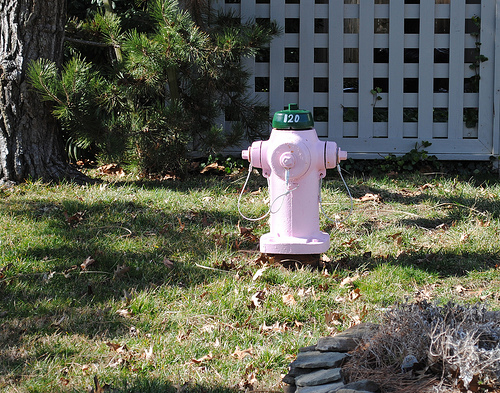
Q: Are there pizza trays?
A: No, there are no pizza trays.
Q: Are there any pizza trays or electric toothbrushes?
A: No, there are no pizza trays or electric toothbrushes.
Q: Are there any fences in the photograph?
A: Yes, there is a fence.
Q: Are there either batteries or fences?
A: Yes, there is a fence.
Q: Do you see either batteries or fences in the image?
A: Yes, there is a fence.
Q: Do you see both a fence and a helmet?
A: No, there is a fence but no helmets.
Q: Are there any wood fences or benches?
A: Yes, there is a wood fence.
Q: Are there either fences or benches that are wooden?
A: Yes, the fence is wooden.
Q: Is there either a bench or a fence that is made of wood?
A: Yes, the fence is made of wood.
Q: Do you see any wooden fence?
A: Yes, there is a wood fence.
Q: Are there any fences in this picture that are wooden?
A: Yes, there is a fence that is wooden.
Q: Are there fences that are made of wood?
A: Yes, there is a fence that is made of wood.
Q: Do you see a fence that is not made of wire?
A: Yes, there is a fence that is made of wood.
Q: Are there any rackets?
A: No, there are no rackets.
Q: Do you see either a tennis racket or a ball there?
A: No, there are no rackets or balls.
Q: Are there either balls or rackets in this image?
A: No, there are no rackets or balls.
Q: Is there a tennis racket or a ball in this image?
A: No, there are no rackets or balls.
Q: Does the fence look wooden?
A: Yes, the fence is wooden.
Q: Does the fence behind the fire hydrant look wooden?
A: Yes, the fence is wooden.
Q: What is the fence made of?
A: The fence is made of wood.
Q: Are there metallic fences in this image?
A: No, there is a fence but it is wooden.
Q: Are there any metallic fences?
A: No, there is a fence but it is wooden.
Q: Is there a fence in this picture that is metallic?
A: No, there is a fence but it is wooden.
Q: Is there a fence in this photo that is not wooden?
A: No, there is a fence but it is wooden.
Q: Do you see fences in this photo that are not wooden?
A: No, there is a fence but it is wooden.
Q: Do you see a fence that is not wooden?
A: No, there is a fence but it is wooden.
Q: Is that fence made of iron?
A: No, the fence is made of wood.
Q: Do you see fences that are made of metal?
A: No, there is a fence but it is made of wood.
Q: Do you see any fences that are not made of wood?
A: No, there is a fence but it is made of wood.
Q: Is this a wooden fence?
A: Yes, this is a wooden fence.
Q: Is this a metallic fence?
A: No, this is a wooden fence.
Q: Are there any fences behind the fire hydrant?
A: Yes, there is a fence behind the fire hydrant.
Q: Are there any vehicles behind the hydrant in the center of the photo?
A: No, there is a fence behind the hydrant.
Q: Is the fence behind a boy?
A: No, the fence is behind the hydrant.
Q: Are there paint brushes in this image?
A: No, there are no paint brushes.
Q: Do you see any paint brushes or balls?
A: No, there are no paint brushes or balls.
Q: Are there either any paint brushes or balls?
A: No, there are no paint brushes or balls.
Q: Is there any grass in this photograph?
A: Yes, there is grass.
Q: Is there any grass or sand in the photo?
A: Yes, there is grass.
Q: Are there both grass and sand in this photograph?
A: No, there is grass but no sand.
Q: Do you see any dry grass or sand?
A: Yes, there is dry grass.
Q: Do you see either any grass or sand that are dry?
A: Yes, the grass is dry.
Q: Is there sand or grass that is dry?
A: Yes, the grass is dry.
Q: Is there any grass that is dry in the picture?
A: Yes, there is dry grass.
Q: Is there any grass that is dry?
A: Yes, there is grass that is dry.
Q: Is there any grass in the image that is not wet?
A: Yes, there is dry grass.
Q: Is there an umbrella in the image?
A: No, there are no umbrellas.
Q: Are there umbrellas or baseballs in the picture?
A: No, there are no umbrellas or baseballs.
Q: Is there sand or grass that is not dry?
A: No, there is grass but it is dry.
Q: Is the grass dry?
A: Yes, the grass is dry.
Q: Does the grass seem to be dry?
A: Yes, the grass is dry.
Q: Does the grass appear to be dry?
A: Yes, the grass is dry.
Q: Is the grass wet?
A: No, the grass is dry.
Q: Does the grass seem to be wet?
A: No, the grass is dry.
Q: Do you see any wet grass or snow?
A: No, there is grass but it is dry.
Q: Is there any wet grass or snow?
A: No, there is grass but it is dry.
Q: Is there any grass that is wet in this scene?
A: No, there is grass but it is dry.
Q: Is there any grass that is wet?
A: No, there is grass but it is dry.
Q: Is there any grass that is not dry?
A: No, there is grass but it is dry.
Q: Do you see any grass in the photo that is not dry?
A: No, there is grass but it is dry.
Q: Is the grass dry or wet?
A: The grass is dry.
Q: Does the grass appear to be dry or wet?
A: The grass is dry.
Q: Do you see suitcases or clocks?
A: No, there are no clocks or suitcases.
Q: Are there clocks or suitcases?
A: No, there are no clocks or suitcases.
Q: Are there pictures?
A: No, there are no pictures.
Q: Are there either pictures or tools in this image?
A: No, there are no pictures or tools.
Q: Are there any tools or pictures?
A: No, there are no pictures or tools.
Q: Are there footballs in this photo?
A: No, there are no footballs.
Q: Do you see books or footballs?
A: No, there are no footballs or books.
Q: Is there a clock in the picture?
A: No, there are no clocks.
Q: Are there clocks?
A: No, there are no clocks.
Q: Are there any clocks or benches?
A: No, there are no clocks or benches.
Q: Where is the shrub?
A: The shrub is at the trunk.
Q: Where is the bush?
A: The shrub is at the trunk.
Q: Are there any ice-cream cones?
A: No, there are no ice-cream cones.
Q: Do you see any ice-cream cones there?
A: No, there are no ice-cream cones.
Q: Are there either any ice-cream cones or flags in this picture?
A: No, there are no ice-cream cones or flags.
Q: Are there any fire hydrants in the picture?
A: Yes, there is a fire hydrant.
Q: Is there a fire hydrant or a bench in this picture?
A: Yes, there is a fire hydrant.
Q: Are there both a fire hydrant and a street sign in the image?
A: No, there is a fire hydrant but no street signs.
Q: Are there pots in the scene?
A: No, there are no pots.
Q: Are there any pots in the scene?
A: No, there are no pots.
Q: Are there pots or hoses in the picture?
A: No, there are no pots or hoses.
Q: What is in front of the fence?
A: The hydrant is in front of the fence.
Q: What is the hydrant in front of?
A: The hydrant is in front of the fence.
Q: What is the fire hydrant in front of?
A: The hydrant is in front of the fence.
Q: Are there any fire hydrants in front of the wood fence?
A: Yes, there is a fire hydrant in front of the fence.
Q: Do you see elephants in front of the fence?
A: No, there is a fire hydrant in front of the fence.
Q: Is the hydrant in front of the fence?
A: Yes, the hydrant is in front of the fence.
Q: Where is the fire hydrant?
A: The fire hydrant is in the grass.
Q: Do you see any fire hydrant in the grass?
A: Yes, there is a fire hydrant in the grass.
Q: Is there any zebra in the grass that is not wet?
A: No, there is a fire hydrant in the grass.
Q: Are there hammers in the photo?
A: No, there are no hammers.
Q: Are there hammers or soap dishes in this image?
A: No, there are no hammers or soap dishes.